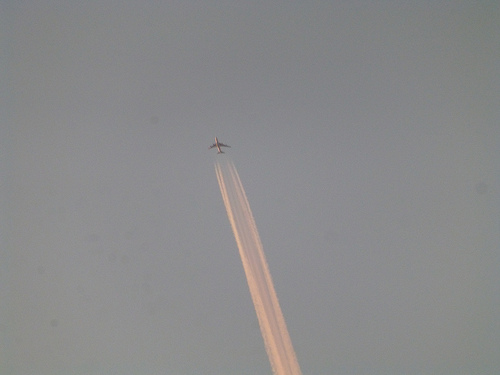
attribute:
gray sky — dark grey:
[0, 0, 500, 169]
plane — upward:
[207, 137, 233, 158]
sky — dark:
[85, 31, 398, 103]